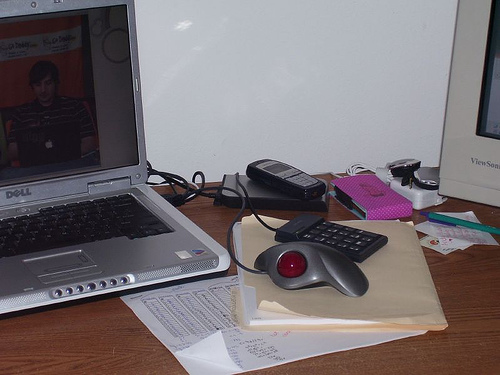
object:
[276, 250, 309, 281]
ball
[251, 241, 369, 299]
mouse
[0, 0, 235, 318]
computer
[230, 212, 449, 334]
file folder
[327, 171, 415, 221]
case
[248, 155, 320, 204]
phone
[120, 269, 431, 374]
paper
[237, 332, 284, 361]
scribble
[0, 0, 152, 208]
monitor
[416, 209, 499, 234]
pen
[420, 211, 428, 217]
blue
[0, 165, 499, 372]
desk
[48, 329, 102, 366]
grain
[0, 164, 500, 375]
wood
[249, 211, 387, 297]
objects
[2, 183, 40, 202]
dell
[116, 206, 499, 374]
paperwork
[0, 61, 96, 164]
man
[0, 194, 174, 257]
keyboard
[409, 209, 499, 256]
papers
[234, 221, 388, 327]
papers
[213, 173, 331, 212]
hard drive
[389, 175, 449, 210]
charger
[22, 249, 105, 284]
trackpad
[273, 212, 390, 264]
keypad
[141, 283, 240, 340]
columns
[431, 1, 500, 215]
monitor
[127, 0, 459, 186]
wall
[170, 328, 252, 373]
edge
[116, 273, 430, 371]
piece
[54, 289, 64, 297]
buttons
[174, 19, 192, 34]
spot